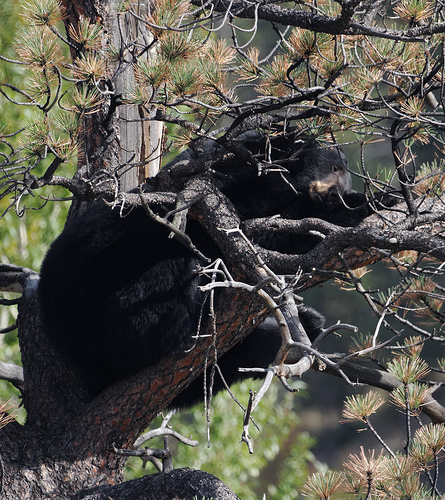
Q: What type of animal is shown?
A: Bear.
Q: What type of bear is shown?
A: Black bear.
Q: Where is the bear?
A: In the tree.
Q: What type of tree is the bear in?
A: Pine tree.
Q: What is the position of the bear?
A: Laying down.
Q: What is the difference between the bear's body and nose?
A: Different colors.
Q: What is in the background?
A: Trees.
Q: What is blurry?
A: Background.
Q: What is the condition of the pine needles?
A: Turning brown.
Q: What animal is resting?
A: A bear.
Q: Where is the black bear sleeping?
A: In a tree.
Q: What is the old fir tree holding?
A: Bear.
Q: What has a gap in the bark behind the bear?
A: Tree.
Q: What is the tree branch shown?
A: Empty.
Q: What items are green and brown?
A: Pines.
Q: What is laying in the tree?
A: Black bear.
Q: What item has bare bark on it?
A: Tree branches.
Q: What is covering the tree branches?
A: Needles.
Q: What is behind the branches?
A: Blurry green background.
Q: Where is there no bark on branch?
A: Behind pine needles.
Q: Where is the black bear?
A: Laying on tree branch.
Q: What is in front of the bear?
A: Branches of the pine tree.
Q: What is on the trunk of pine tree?
A: Black bear.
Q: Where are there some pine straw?
A: On branches.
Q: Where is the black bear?
A: Lying on a limb.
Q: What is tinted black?
A: Fur of the bear.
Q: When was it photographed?
A: During the day.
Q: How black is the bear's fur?
A: Onyx black.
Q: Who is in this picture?
A: Nobody.